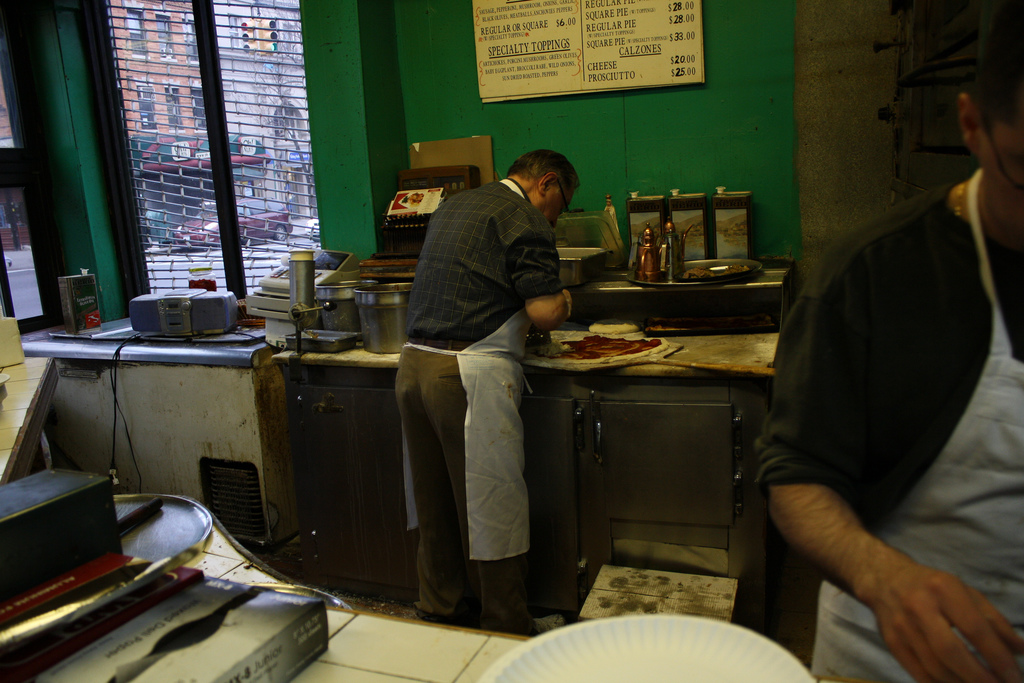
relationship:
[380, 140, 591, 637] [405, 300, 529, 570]
man wears apron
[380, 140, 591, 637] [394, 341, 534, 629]
man wears pants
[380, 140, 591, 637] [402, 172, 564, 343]
man wears gray shirt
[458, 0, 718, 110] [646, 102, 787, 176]
menu hanging on wall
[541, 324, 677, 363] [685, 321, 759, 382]
pizza sitting on counter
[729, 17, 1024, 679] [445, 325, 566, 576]
man in apron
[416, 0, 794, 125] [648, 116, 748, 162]
menu on wall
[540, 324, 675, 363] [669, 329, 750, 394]
pizza on counter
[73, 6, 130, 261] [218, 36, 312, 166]
framed window and blinds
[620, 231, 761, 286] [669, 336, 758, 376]
tray on counter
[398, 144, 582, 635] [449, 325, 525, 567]
chef in a apron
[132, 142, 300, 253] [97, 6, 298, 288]
red car outside window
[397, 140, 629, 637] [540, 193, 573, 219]
man in glasses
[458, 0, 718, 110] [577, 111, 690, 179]
menu on wall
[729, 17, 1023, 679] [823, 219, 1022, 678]
man wearing an apron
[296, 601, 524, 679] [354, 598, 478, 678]
white tiles on counter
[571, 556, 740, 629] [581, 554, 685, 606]
white tiles on floor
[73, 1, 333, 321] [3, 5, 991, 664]
window at back of room